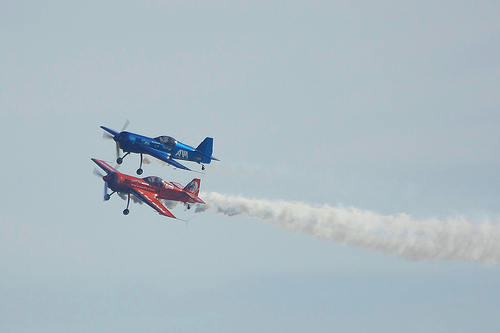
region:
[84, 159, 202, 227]
this is a plane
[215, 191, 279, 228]
this is smoke from a plane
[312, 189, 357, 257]
this is smoke from a plane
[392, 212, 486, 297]
this is smoke from a plane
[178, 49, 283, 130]
the sky is gray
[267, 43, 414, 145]
the sky is gray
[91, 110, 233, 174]
This is an aircraft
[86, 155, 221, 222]
This is an aircraft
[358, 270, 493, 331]
Section of the sky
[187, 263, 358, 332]
Section of the sky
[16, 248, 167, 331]
Section of the sky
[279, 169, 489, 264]
Section of the sky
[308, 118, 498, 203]
Section of the sky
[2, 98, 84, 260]
Section of the sky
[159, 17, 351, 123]
Section of the sky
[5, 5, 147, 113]
Section of the sky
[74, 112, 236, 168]
a blue air plane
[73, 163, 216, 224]
a red plane in sky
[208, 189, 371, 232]
white smoke coming from plane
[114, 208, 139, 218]
left front wheel on plane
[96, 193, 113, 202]
right front wheel on plane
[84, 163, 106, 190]
the front propellers on plane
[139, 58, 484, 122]
the gray blue sky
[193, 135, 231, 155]
a blue tail fin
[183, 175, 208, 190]
a red tail fin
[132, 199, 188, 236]
a left red wing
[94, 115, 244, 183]
this is a plane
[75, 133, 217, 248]
this is a plane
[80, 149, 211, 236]
the plane is red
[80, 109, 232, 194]
the plane is blue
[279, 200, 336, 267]
smoke from the train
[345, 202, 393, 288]
smoke from the train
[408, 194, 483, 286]
smoke from the train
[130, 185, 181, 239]
a wing on the plane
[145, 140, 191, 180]
a wing on the plane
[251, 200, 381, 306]
Section of the sky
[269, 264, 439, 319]
Section of the sky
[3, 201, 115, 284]
Section of the sky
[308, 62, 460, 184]
Section of the sky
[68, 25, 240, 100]
Section of the sky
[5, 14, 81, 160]
Section of the sky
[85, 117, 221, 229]
two planes in the sky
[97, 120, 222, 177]
a blue plane in the sky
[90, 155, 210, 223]
a red plane in the sky